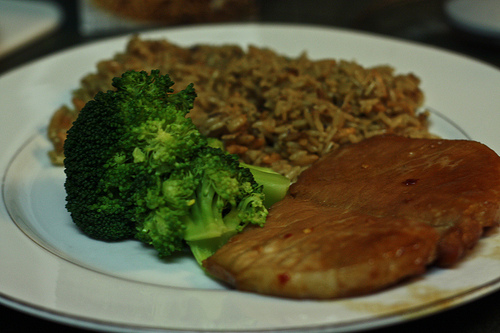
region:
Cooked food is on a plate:
[3, 11, 499, 313]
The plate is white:
[0, 22, 497, 332]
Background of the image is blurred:
[3, 0, 498, 38]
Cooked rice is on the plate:
[96, 36, 433, 173]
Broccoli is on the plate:
[44, 69, 312, 268]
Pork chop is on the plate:
[222, 126, 496, 313]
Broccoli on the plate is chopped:
[54, 66, 308, 283]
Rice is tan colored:
[95, 35, 403, 162]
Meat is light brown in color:
[208, 115, 498, 310]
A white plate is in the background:
[416, 0, 499, 40]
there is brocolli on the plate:
[47, 56, 239, 259]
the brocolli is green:
[101, 111, 232, 228]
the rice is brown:
[208, 79, 383, 138]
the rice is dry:
[213, 88, 312, 131]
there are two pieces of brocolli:
[58, 90, 271, 260]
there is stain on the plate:
[366, 262, 477, 330]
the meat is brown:
[249, 112, 485, 312]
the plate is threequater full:
[17, 71, 487, 331]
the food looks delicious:
[49, 67, 454, 300]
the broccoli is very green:
[61, 85, 299, 280]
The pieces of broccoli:
[62, 71, 292, 266]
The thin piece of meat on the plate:
[198, 127, 498, 298]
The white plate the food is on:
[2, 19, 497, 331]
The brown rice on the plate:
[45, 28, 432, 190]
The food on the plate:
[39, 27, 499, 304]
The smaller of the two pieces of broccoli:
[129, 139, 268, 270]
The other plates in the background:
[2, 2, 498, 60]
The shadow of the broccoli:
[13, 184, 176, 286]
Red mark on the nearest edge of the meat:
[276, 271, 298, 288]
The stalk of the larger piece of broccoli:
[229, 158, 293, 202]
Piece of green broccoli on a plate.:
[135, 147, 268, 267]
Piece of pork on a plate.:
[201, 131, 498, 299]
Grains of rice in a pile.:
[263, 70, 298, 115]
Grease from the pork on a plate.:
[361, 296, 413, 316]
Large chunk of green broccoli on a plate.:
[60, 70, 298, 269]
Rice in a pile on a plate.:
[343, 61, 425, 138]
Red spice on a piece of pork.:
[275, 272, 291, 285]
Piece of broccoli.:
[142, 207, 182, 251]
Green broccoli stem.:
[227, 154, 295, 211]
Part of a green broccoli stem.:
[186, 200, 238, 267]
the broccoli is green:
[114, 103, 266, 218]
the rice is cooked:
[186, 42, 366, 160]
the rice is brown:
[157, 48, 431, 168]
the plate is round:
[22, 43, 359, 325]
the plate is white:
[37, 40, 400, 325]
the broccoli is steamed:
[69, 62, 271, 247]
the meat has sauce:
[200, 128, 448, 324]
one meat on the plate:
[207, 113, 441, 324]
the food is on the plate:
[47, 18, 378, 329]